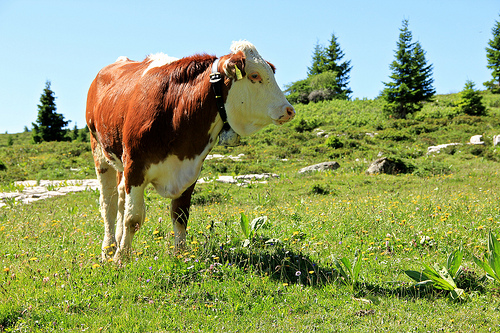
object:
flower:
[270, 267, 303, 277]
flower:
[307, 267, 317, 274]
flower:
[88, 260, 101, 276]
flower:
[39, 272, 63, 287]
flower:
[383, 210, 451, 266]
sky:
[2, 2, 498, 121]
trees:
[283, 18, 436, 102]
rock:
[298, 157, 340, 173]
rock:
[466, 133, 485, 147]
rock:
[312, 126, 335, 138]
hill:
[0, 89, 499, 331]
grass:
[5, 128, 495, 325]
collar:
[207, 52, 232, 132]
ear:
[220, 53, 247, 82]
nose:
[284, 105, 298, 118]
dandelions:
[0, 150, 499, 331]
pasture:
[332, 93, 485, 288]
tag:
[231, 64, 247, 83]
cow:
[71, 38, 296, 264]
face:
[236, 80, 272, 115]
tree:
[31, 69, 76, 143]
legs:
[93, 150, 208, 272]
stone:
[366, 155, 414, 174]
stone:
[464, 133, 484, 145]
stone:
[315, 130, 328, 139]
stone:
[298, 160, 342, 173]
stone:
[424, 141, 464, 152]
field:
[0, 89, 499, 331]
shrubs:
[363, 86, 494, 132]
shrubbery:
[275, 33, 341, 132]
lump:
[232, 40, 258, 57]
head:
[211, 40, 297, 145]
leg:
[170, 187, 193, 264]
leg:
[112, 171, 148, 266]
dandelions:
[378, 222, 441, 257]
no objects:
[314, 223, 335, 229]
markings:
[122, 206, 146, 239]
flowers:
[0, 225, 205, 299]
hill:
[302, 92, 481, 162]